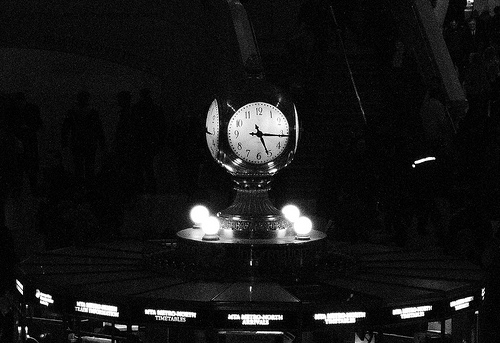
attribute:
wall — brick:
[23, 32, 154, 223]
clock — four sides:
[221, 103, 314, 178]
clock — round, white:
[226, 100, 288, 167]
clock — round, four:
[201, 70, 301, 244]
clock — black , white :
[203, 81, 301, 179]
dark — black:
[28, 25, 159, 173]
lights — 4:
[184, 200, 316, 241]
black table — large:
[130, 244, 401, 340]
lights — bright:
[161, 197, 298, 258]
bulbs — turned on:
[174, 206, 331, 235]